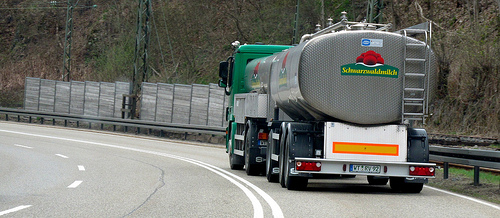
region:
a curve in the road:
[155, 28, 484, 216]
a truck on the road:
[198, 25, 430, 213]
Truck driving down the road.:
[210, 17, 492, 182]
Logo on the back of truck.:
[335, 49, 405, 83]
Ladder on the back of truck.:
[396, 24, 438, 136]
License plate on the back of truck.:
[348, 163, 383, 175]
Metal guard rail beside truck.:
[431, 135, 498, 190]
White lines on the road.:
[4, 132, 114, 216]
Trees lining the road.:
[66, 13, 226, 106]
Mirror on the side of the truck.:
[215, 53, 235, 96]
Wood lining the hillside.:
[21, 73, 144, 117]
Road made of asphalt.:
[110, 159, 162, 216]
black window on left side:
[214, 50, 234, 90]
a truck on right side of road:
[206, 7, 447, 197]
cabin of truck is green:
[207, 32, 268, 133]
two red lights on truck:
[290, 151, 440, 181]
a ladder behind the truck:
[400, 21, 432, 132]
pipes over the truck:
[290, 2, 396, 38]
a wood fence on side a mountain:
[18, 70, 220, 130]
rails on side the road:
[5, 101, 220, 137]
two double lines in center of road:
[165, 160, 287, 216]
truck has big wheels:
[219, 116, 305, 188]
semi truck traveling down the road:
[213, 15, 450, 183]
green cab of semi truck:
[214, 38, 271, 148]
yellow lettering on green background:
[338, 64, 398, 79]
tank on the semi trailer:
[263, 30, 438, 123]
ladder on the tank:
[396, 25, 428, 125]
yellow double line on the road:
[0, 117, 287, 217]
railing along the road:
[7, 104, 499, 180]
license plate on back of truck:
[349, 157, 386, 172]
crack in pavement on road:
[108, 150, 178, 215]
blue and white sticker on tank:
[355, 30, 387, 48]